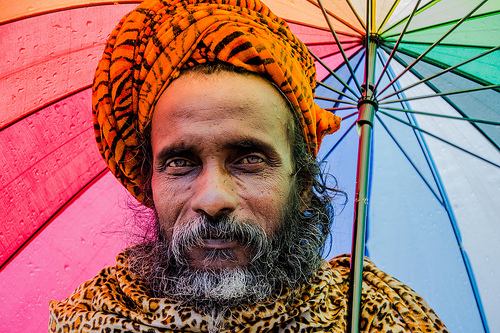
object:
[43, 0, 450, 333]
man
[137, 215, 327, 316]
beard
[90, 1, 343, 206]
turban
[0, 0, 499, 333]
umbrella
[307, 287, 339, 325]
scarf